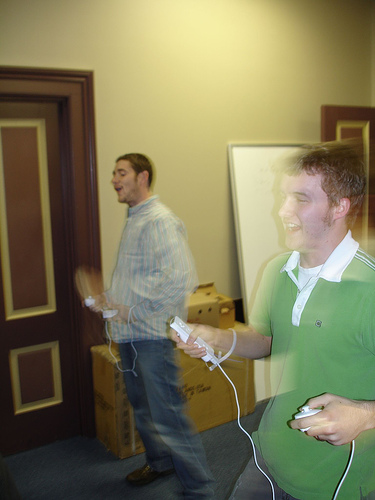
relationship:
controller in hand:
[285, 376, 353, 445] [284, 380, 374, 443]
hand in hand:
[284, 380, 374, 443] [105, 298, 137, 325]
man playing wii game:
[82, 153, 219, 500] [75, 287, 356, 496]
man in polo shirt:
[166, 145, 374, 498] [247, 227, 373, 495]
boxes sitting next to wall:
[92, 279, 327, 426] [5, 0, 363, 402]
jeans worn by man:
[119, 339, 216, 499] [82, 152, 218, 498]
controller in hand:
[87, 294, 114, 319] [78, 287, 127, 330]